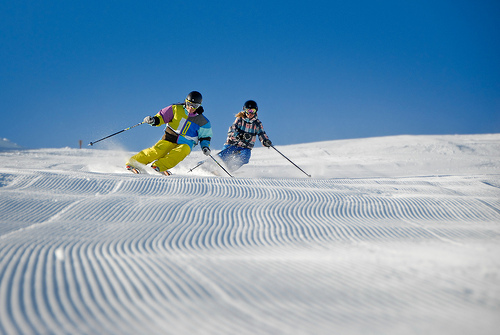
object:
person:
[218, 99, 275, 174]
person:
[124, 90, 213, 173]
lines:
[190, 195, 299, 241]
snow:
[0, 133, 500, 335]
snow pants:
[125, 140, 191, 173]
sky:
[0, 0, 500, 153]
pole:
[203, 149, 235, 178]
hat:
[243, 100, 259, 114]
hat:
[186, 90, 203, 104]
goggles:
[244, 108, 257, 115]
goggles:
[185, 98, 202, 110]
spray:
[100, 131, 127, 171]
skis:
[125, 165, 142, 175]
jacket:
[147, 102, 213, 152]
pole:
[270, 141, 319, 181]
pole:
[86, 117, 151, 147]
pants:
[216, 144, 252, 173]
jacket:
[224, 114, 273, 150]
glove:
[261, 137, 273, 147]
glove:
[142, 115, 157, 125]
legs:
[124, 134, 179, 166]